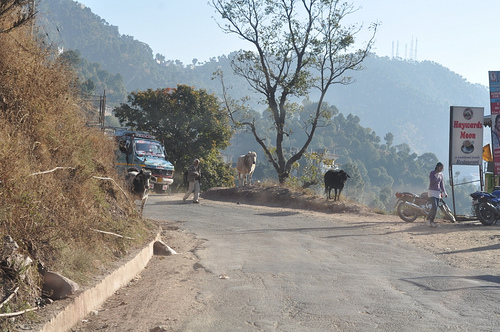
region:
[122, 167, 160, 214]
black and white cow on road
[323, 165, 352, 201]
black cow near tree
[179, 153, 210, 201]
person walking on road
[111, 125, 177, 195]
large vehicle stopped on road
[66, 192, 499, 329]
the road is gray and dusty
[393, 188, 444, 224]
motorcycle parked on sand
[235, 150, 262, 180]
white cow near bush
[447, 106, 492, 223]
white sign next to motorcycle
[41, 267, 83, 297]
rock at base of hillside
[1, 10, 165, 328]
hillside next to road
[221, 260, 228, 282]
white mark is spotted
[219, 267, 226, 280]
white mark is spotted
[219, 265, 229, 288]
white mark is spotted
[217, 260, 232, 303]
white mark is spotted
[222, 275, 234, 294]
white mark is spotted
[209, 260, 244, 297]
white mark is spotted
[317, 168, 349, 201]
Black cow by side of road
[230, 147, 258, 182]
white cow by side of road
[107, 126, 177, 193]
blue truck in street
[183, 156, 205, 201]
man walkiing in street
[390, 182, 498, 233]
two motorcycles parked in front of store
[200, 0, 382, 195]
tree between two cows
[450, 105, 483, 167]
a sign for a store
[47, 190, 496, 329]
the asphalt on the street is cracked and dusty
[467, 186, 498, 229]
a blue motorcycle in front of a sign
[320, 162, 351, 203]
a small black calf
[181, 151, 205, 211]
man on the road walking toward the animals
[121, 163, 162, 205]
a cow walking down the road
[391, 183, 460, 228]
a motorcycle on the side of the road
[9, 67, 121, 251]
brush on the side of the road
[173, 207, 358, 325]
the road for animals and vehicles to go down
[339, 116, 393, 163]
tops of trees growing on the hill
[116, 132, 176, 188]
blue truck coming down the road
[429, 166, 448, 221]
motocycles owner on the side of the road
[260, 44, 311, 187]
a tree growing on the edge of the road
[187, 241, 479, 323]
a semi paved road in a mountainous area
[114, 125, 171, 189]
a blue van driving down a mountain road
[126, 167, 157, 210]
a cow on the side of the road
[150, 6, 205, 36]
a partially hazy sky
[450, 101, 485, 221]
a large sign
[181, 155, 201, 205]
a person walking down the road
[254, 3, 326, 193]
a large tree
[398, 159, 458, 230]
a person standing in front of a motorcycle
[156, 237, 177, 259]
a large rock on the side of the road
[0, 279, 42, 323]
large twigs